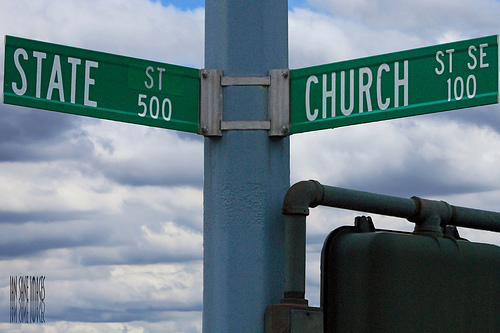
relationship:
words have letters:
[14, 47, 103, 114] [305, 63, 412, 125]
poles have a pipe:
[282, 181, 499, 319] [273, 172, 466, 328]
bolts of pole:
[198, 72, 216, 138] [204, 1, 292, 331]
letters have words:
[305, 63, 412, 125] [14, 47, 103, 114]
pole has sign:
[204, 1, 292, 331] [6, 34, 207, 136]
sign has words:
[6, 34, 207, 136] [14, 47, 103, 114]